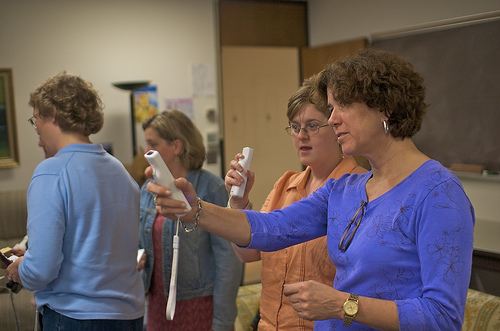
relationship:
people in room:
[6, 49, 475, 330] [1, 1, 500, 330]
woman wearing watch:
[145, 46, 479, 330] [340, 290, 360, 327]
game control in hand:
[230, 145, 255, 198] [223, 152, 256, 200]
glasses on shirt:
[338, 200, 368, 252] [237, 156, 475, 329]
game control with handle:
[143, 149, 192, 218] [164, 233, 180, 322]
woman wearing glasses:
[223, 67, 372, 331] [285, 121, 334, 138]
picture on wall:
[1, 67, 21, 171] [1, 1, 308, 196]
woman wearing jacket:
[138, 108, 245, 330] [137, 167, 243, 329]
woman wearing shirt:
[137, 109, 244, 331] [18, 144, 146, 321]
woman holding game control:
[145, 46, 479, 330] [144, 149, 193, 218]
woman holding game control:
[223, 67, 372, 331] [230, 146, 254, 199]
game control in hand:
[144, 149, 193, 218] [144, 163, 200, 224]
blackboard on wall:
[368, 12, 499, 182] [306, 3, 499, 300]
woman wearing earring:
[145, 46, 479, 330] [380, 117, 391, 136]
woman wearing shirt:
[223, 67, 372, 331] [257, 154, 372, 330]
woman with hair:
[145, 46, 479, 330] [315, 50, 430, 140]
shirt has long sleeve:
[18, 144, 146, 321] [18, 168, 68, 293]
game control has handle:
[144, 149, 193, 218] [166, 235, 180, 321]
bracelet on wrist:
[177, 194, 203, 234] [190, 190, 211, 231]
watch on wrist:
[340, 290, 360, 327] [337, 289, 362, 325]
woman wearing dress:
[138, 108, 245, 330] [146, 213, 238, 330]